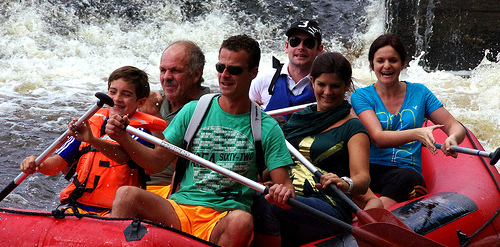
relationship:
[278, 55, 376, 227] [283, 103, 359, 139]
woman wearing a green scarf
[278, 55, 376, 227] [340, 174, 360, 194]
woman wearing a silver watch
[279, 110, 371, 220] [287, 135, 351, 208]
shirt has gold leaf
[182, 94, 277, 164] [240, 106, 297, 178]
straps are draping over shoulder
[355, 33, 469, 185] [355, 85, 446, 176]
woman wearing a blue shirt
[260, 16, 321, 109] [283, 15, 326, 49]
man wearing a nascar hat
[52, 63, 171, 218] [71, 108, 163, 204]
boy wearing an orange life vest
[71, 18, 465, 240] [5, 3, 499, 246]
group of people enjoying rafting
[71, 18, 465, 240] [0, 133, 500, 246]
group of people sitting in a red raft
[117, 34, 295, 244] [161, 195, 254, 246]
man wearing yellow shorts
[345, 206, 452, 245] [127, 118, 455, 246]
bottoms of two paddles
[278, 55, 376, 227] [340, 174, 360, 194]
woman wearing a watch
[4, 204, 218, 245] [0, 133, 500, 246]
front of red raft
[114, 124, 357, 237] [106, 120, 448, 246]
pole on a paddle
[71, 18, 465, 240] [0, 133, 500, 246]
group of people on a red raft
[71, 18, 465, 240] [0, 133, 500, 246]
group of people riding in a red raft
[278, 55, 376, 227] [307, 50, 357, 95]
woman has brown hair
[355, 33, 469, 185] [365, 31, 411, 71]
woman has brown hair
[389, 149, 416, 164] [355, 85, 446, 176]
white writing on a blue shirt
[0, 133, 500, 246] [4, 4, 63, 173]
red raft on top of water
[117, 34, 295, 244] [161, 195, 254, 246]
man wearing shorts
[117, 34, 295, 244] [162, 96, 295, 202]
man wearing a shirt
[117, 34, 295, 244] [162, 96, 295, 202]
man wearing a green shirt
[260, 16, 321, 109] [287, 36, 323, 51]
man wearing sunglasses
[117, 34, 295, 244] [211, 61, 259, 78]
man wearing sunglasses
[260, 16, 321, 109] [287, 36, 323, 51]
man wearing black sunglasses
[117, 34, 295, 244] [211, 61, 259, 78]
man wearing black sunglasses